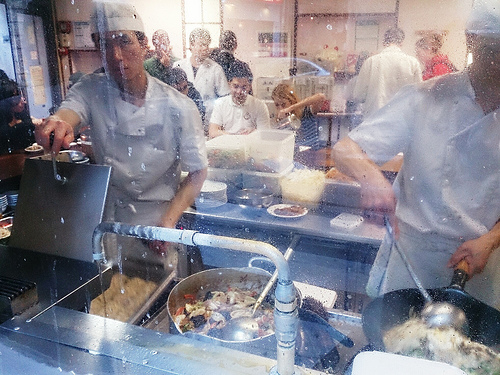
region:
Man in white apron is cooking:
[321, 0, 496, 305]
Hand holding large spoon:
[350, 166, 410, 236]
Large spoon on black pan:
[376, 195, 466, 335]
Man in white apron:
[30, 0, 208, 265]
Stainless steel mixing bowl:
[230, 185, 271, 208]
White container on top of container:
[246, 125, 299, 170]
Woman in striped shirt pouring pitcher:
[267, 85, 325, 147]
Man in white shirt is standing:
[171, 25, 227, 101]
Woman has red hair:
[263, 82, 323, 150]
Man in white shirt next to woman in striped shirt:
[202, 62, 271, 137]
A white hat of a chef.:
[466, 0, 498, 35]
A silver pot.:
[166, 255, 298, 351]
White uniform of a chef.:
[351, 68, 498, 289]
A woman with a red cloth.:
[415, 29, 459, 79]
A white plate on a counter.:
[266, 202, 308, 220]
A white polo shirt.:
[207, 91, 272, 136]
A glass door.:
[14, 5, 60, 118]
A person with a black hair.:
[1, 80, 37, 149]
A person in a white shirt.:
[172, 54, 233, 99]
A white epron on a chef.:
[381, 230, 498, 310]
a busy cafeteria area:
[21, 13, 484, 351]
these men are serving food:
[61, 18, 498, 193]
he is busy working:
[35, 5, 215, 278]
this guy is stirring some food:
[318, 107, 485, 364]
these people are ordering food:
[135, 20, 260, 101]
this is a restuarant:
[143, 18, 463, 130]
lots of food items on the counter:
[208, 137, 333, 227]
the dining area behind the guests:
[159, 2, 474, 69]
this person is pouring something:
[269, 76, 333, 173]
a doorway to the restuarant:
[3, 3, 64, 130]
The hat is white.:
[83, 7, 152, 37]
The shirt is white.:
[52, 63, 222, 209]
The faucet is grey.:
[78, 216, 318, 367]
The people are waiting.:
[147, 32, 451, 112]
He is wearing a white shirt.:
[208, 86, 270, 126]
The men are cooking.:
[15, 4, 499, 346]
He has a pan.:
[357, 183, 491, 373]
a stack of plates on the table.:
[187, 175, 228, 209]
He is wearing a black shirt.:
[209, 45, 254, 87]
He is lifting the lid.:
[34, 115, 123, 272]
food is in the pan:
[391, 318, 489, 350]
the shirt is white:
[388, 126, 495, 216]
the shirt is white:
[96, 101, 188, 208]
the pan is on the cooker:
[356, 288, 496, 374]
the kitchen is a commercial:
[4, 55, 478, 363]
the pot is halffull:
[182, 286, 269, 348]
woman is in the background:
[416, 41, 452, 68]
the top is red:
[433, 57, 451, 75]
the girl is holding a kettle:
[253, 88, 328, 129]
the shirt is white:
[358, 53, 428, 101]